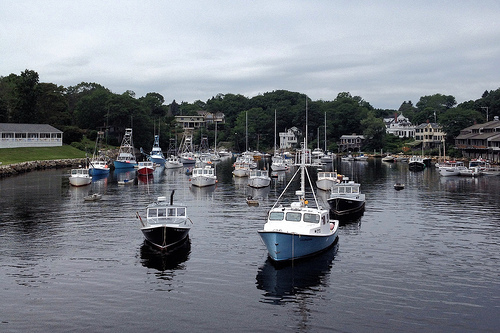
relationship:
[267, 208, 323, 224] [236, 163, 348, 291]
windows on boat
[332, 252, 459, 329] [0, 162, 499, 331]
ripples on water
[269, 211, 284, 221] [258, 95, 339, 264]
window on boat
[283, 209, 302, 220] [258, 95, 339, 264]
window on boat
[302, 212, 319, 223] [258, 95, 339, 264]
window on boat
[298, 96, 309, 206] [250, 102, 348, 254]
mast on boat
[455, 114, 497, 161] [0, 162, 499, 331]
building beside water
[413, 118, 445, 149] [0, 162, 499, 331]
building beside water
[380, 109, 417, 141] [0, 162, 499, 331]
building beside water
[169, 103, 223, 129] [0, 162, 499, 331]
building beside water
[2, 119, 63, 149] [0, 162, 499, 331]
building beside water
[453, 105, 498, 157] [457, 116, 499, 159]
roof on building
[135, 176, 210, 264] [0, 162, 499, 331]
small boat floating in water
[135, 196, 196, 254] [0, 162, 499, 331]
boat floating in water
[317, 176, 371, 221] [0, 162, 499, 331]
boat floating in water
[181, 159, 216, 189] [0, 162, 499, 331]
boat floating in water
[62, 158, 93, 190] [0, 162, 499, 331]
boat floating in water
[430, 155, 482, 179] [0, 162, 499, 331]
boat floating in water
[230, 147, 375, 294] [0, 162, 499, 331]
boat floating in water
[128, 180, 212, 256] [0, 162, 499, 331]
boat floating in water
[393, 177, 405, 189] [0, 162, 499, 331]
boat floating in water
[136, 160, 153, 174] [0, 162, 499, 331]
boat floating in water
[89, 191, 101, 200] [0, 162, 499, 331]
boat floating in water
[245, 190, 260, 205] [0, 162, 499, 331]
boat floating in water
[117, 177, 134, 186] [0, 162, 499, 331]
boat floating in water